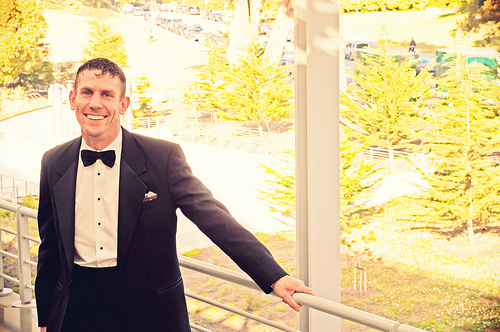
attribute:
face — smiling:
[60, 61, 142, 143]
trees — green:
[354, 47, 499, 276]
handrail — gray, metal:
[180, 201, 499, 330]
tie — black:
[66, 144, 124, 175]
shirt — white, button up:
[68, 134, 124, 276]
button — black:
[97, 197, 99, 199]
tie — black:
[80, 146, 117, 168]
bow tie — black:
[78, 150, 117, 164]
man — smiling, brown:
[32, 56, 312, 327]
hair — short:
[76, 57, 127, 80]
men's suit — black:
[25, 136, 225, 328]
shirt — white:
[23, 140, 236, 317]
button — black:
[92, 191, 104, 203]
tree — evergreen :
[348, 50, 426, 179]